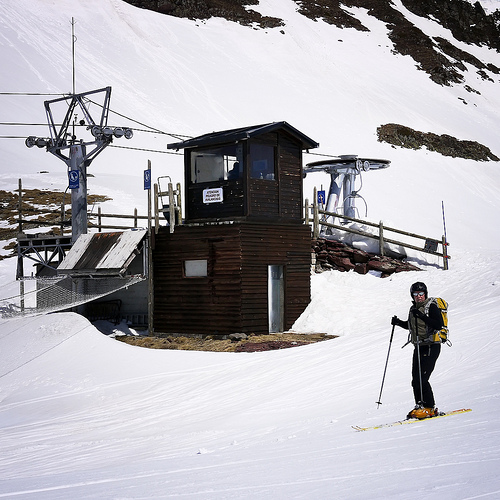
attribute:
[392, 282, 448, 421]
skier — moving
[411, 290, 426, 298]
goggles — gray, shiny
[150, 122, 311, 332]
building — small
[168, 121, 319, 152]
roof — black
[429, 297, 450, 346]
backpack — yellow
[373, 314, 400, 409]
ski pole — long, thin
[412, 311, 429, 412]
ski pole — long, thin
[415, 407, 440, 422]
snow shoe — orange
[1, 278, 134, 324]
net — white, large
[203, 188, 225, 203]
sign — white, small